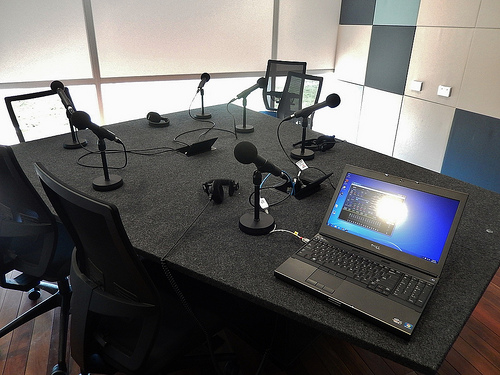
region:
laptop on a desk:
[272, 154, 471, 351]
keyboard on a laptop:
[314, 239, 400, 298]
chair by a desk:
[26, 156, 187, 363]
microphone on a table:
[230, 135, 304, 251]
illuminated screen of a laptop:
[350, 178, 436, 253]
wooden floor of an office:
[462, 311, 497, 358]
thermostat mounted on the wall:
[407, 74, 429, 96]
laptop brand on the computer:
[387, 315, 414, 336]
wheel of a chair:
[18, 281, 48, 311]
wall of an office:
[104, 3, 251, 66]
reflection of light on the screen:
[363, 192, 414, 232]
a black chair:
[31, 163, 121, 288]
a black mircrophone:
[234, 138, 271, 166]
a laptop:
[278, 165, 464, 332]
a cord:
[275, 222, 308, 242]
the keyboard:
[313, 245, 395, 290]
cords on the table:
[140, 137, 176, 160]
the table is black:
[203, 235, 255, 278]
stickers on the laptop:
[391, 315, 411, 331]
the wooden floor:
[10, 339, 47, 364]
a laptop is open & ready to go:
[273, 140, 478, 335]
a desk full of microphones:
[22, 64, 350, 188]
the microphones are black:
[51, 65, 324, 235]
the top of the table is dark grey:
[163, 171, 178, 234]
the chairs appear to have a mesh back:
[266, 53, 329, 118]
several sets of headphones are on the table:
[147, 103, 338, 213]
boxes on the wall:
[407, 78, 470, 107]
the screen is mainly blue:
[349, 176, 448, 253]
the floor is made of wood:
[3, 338, 60, 370]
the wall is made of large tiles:
[364, 6, 491, 153]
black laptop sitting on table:
[269, 168, 477, 310]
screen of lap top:
[318, 173, 458, 253]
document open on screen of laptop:
[326, 178, 412, 242]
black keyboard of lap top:
[302, 233, 393, 294]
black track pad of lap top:
[308, 266, 343, 291]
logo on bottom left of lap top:
[385, 312, 412, 337]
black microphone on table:
[220, 131, 300, 236]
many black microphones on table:
[44, 36, 345, 227]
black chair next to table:
[21, 163, 168, 374]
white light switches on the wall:
[407, 80, 452, 100]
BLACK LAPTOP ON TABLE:
[297, 138, 454, 330]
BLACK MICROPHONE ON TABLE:
[186, 123, 290, 215]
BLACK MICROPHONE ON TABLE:
[83, 103, 143, 185]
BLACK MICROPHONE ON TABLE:
[50, 85, 78, 147]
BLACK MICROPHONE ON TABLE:
[186, 64, 221, 121]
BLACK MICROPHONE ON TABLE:
[230, 76, 263, 138]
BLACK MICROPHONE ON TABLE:
[292, 92, 357, 197]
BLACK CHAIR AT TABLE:
[31, 165, 121, 294]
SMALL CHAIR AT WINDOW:
[13, 89, 70, 134]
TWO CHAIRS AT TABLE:
[255, 58, 345, 197]